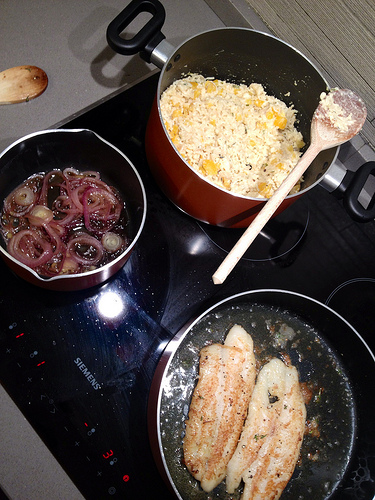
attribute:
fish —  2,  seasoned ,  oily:
[183, 326, 305, 493]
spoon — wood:
[202, 77, 362, 290]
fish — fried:
[179, 309, 262, 491]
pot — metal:
[144, 60, 328, 208]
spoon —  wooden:
[210, 76, 369, 324]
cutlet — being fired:
[183, 323, 257, 492]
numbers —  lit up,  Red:
[13, 328, 130, 482]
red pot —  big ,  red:
[0, 125, 146, 299]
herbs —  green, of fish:
[233, 109, 293, 178]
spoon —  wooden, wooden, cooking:
[211, 81, 369, 282]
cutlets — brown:
[198, 341, 302, 496]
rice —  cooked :
[158, 72, 313, 200]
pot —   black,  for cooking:
[1, 126, 148, 292]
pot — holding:
[141, 20, 345, 208]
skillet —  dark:
[145, 286, 374, 499]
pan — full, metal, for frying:
[140, 282, 374, 496]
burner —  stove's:
[198, 200, 311, 260]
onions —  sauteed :
[5, 165, 113, 257]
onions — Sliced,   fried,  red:
[2, 167, 126, 268]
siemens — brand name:
[74, 352, 104, 398]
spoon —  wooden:
[2, 53, 71, 103]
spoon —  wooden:
[0, 64, 48, 103]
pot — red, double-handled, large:
[141, 24, 353, 236]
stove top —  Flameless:
[0, 67, 375, 495]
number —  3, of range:
[102, 448, 112, 461]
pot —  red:
[149, 22, 345, 231]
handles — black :
[129, 330, 171, 441]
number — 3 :
[95, 443, 116, 458]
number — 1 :
[31, 355, 48, 369]